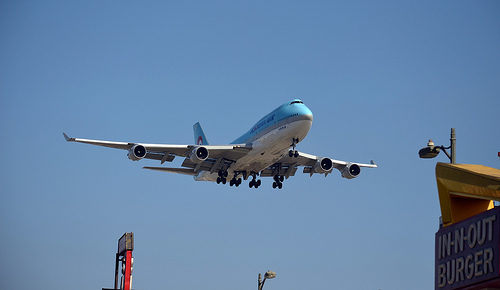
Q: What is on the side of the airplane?
A: That is the airplane's wing.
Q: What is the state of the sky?
A: The sky is clear.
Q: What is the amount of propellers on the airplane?
A: There are four propellers.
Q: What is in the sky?
A: A jet.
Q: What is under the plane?
A: Landing gear.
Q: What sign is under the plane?
A: In-N-Out Burger.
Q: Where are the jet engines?
A: Under the wings.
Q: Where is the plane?
A: In the sky.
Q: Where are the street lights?
A: Below the plane.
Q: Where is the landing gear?
A: Under the plane.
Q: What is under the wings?
A: Plane engines.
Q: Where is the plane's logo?
A: On the tail.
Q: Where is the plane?
A: Air.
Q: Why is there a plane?
A: Flying.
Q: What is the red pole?
A: A sign.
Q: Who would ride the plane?
A: People.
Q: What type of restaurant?
A: Burger joint.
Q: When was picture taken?
A: Daytime.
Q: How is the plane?
A: Flying.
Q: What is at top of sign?
A: Light.